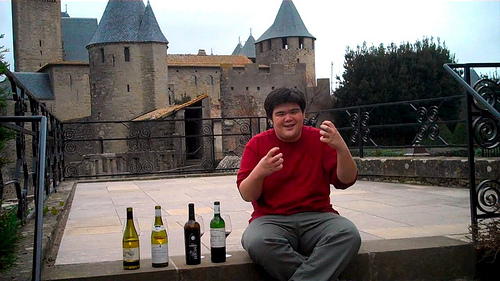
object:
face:
[270, 101, 306, 141]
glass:
[210, 201, 227, 262]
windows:
[123, 46, 130, 62]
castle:
[51, 36, 229, 98]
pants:
[240, 210, 364, 281]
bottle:
[121, 207, 142, 270]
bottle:
[150, 205, 170, 268]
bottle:
[209, 201, 223, 264]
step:
[38, 234, 498, 281]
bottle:
[182, 203, 202, 265]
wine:
[187, 231, 199, 262]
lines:
[359, 186, 446, 244]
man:
[236, 87, 364, 279]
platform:
[352, 180, 471, 232]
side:
[208, 216, 227, 264]